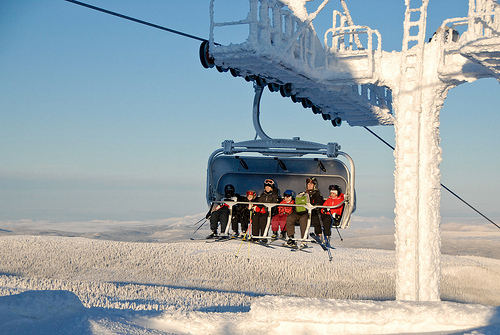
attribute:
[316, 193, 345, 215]
jacket — red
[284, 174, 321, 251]
person — sitting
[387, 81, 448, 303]
pillar — snowy, covered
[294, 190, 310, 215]
backpack — green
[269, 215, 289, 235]
pants — black, red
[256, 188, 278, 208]
coat — black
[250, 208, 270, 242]
bottom — black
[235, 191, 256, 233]
child — sitting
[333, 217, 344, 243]
pole — black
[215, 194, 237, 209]
shirt — white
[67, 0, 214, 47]
cable — long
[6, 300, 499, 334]
ground — snowy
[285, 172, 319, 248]
skier — red